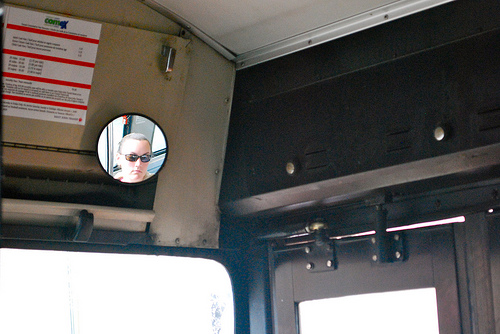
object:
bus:
[0, 7, 499, 334]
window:
[0, 252, 233, 334]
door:
[270, 216, 500, 334]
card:
[0, 7, 104, 127]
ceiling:
[147, 0, 451, 64]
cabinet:
[267, 158, 316, 186]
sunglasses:
[125, 154, 151, 162]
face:
[119, 143, 150, 182]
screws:
[434, 127, 445, 141]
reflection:
[97, 115, 168, 184]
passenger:
[114, 132, 155, 183]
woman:
[116, 133, 155, 183]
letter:
[3, 3, 101, 125]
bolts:
[305, 232, 404, 272]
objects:
[259, 193, 469, 297]